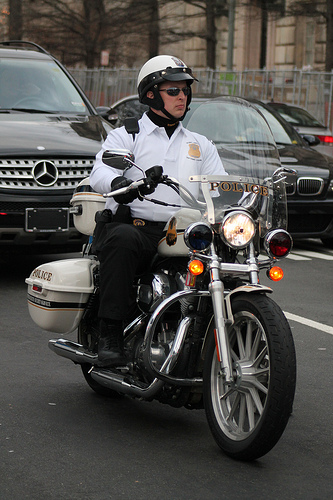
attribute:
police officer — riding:
[88, 54, 230, 360]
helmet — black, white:
[136, 54, 199, 107]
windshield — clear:
[178, 98, 288, 228]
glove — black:
[113, 168, 164, 202]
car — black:
[108, 96, 332, 249]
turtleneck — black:
[144, 108, 180, 136]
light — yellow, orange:
[267, 266, 285, 282]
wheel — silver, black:
[204, 293, 296, 461]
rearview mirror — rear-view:
[102, 149, 134, 167]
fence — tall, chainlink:
[63, 67, 333, 127]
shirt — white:
[92, 112, 227, 223]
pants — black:
[92, 213, 160, 338]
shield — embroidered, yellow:
[189, 141, 202, 159]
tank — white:
[26, 256, 100, 332]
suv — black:
[0, 39, 125, 252]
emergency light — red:
[265, 230, 292, 259]